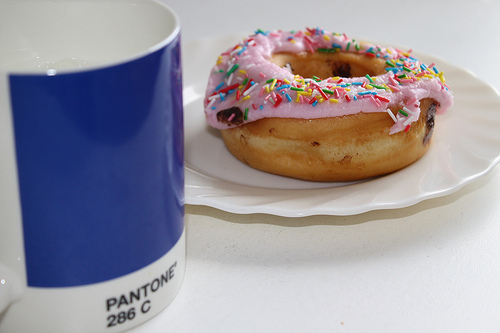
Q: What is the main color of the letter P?
A: Black.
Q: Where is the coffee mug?
A: In front of the donut.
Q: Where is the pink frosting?
A: On the donut.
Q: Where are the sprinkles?
A: On the frosted donut.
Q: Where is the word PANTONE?
A: On the bottom of the mug.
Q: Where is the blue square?
A: On the mug.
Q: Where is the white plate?
A: Under the donut.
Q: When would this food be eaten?
A: For breakfast.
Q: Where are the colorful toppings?
A: On the donut.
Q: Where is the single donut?
A: On the white plate.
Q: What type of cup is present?
A: Coffee.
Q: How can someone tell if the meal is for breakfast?
A: Doughnut and coffee.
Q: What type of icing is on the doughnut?
A: Pink.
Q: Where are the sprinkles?
A: Doughnut.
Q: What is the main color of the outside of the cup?
A: Blue.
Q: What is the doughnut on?
A: Saucer.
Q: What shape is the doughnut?
A: Circular.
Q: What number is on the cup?
A: 286.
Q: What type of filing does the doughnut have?
A: Chocolate.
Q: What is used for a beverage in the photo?
A: A mug.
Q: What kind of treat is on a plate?
A: A doughnut.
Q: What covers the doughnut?
A: Pink frosting.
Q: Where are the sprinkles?
A: On frosting.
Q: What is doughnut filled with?
A: Chocolate.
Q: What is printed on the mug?
A: Pantone 286 c.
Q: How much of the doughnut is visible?
A: The whole doughnut.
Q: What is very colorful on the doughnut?
A: Sprinkles.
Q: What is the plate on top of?
A: A white table.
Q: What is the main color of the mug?
A: Blue.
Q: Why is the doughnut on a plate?
A: Not to make a mess.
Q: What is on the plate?
A: A doughnut.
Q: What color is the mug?
A: Blue.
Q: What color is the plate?
A: White.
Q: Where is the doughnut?
A: On a plate.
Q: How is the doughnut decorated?
A: With sprinkles.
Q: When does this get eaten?
A: For breakfast.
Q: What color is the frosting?
A: Pink.